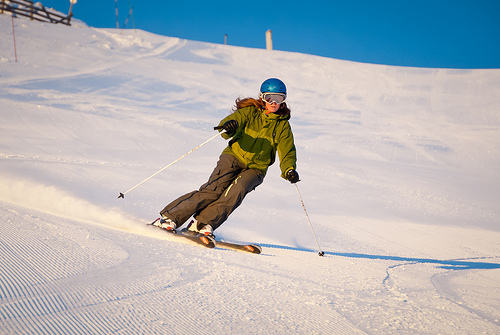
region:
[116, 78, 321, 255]
A woman is skiing.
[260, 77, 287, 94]
The woman's helmet is blue.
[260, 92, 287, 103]
The woman wears goggles.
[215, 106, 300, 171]
The woman's jacket is green.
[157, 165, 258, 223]
The woman's pants are brown.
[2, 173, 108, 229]
The skis make a trail in the snow.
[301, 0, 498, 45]
The sky is blue.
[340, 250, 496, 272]
The skier's shadow is on the snow.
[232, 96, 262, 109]
The woman has red hair.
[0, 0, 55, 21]
A fence is in the background.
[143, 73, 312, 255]
A woman skiing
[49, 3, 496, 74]
A bright blue sky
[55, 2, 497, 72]
A sky with no clouds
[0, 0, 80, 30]
A black fence in the background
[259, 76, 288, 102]
A woman in a blue helmet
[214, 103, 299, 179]
A woman in a green jacket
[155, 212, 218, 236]
A woman in white boots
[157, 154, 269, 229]
A woman in black pants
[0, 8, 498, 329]
Snow on the ground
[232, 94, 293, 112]
A woman with long hair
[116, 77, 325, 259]
the woman skiing down the hill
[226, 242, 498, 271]
the shadow on the snow from the woman skiing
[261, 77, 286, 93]
the blue helmet on the woman's head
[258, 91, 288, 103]
the protective eyewear on the woman's face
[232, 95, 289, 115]
the hair from the woman's head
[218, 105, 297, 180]
the green jacket the woman is wearing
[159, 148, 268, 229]
the ski pants on the woman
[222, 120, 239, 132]
the glove on the woman's right hand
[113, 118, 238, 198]
the ski pole in the woman's right hand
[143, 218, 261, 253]
the two skis under the woman's feet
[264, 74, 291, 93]
Blue helmet in the photo.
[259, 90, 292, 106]
Goggles in the photo.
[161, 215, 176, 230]
White shoe in the photo.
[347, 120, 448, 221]
Snow-capped surface in the photo.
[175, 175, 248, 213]
Brown pants in the photo.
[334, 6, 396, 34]
Blue sky in the photo.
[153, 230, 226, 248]
Skating gear in the photo.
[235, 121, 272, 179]
Green jacket in the photo.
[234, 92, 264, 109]
Blonde hair in the photo.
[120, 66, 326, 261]
A person skating in the photo.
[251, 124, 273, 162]
the coat is olive green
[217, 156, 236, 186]
the pants are gray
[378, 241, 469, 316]
the snow has tracks on it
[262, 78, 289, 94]
the helmet is blue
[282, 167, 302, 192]
the glove is black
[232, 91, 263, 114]
her hair is red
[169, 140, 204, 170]
the ski pole is white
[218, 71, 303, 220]
she is going down hill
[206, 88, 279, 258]
she is swirving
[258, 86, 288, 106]
the goggles are gray